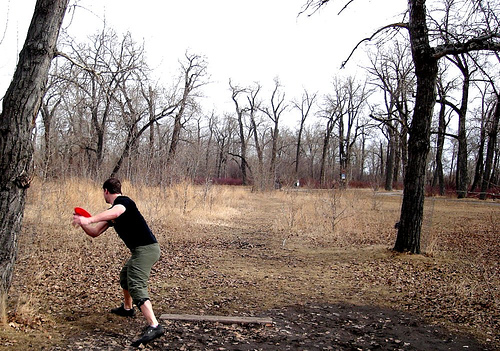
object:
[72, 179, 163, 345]
man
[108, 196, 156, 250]
shirt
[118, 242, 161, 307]
shorts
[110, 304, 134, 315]
shoe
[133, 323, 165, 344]
shoe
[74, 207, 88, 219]
frisbee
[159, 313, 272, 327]
plywood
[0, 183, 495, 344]
ground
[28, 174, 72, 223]
grass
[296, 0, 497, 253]
tree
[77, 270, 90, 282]
leaves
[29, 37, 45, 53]
knot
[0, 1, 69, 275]
tree trunk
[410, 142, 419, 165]
bark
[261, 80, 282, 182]
tree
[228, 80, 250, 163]
tree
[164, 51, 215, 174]
tree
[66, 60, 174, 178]
tree